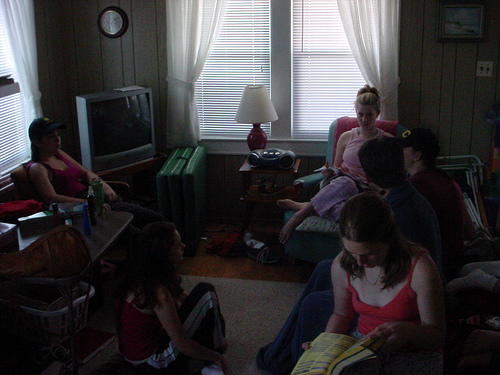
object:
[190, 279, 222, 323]
knee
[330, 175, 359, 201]
knee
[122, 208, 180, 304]
hair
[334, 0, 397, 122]
curtains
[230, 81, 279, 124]
lamp shade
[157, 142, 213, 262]
tables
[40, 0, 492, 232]
wall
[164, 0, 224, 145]
curtain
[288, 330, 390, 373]
book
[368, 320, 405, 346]
hand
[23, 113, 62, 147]
cap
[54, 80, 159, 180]
television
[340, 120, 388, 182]
shirt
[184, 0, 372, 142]
window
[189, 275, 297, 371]
carpet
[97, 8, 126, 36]
clock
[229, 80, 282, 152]
lamp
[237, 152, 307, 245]
table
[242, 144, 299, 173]
stereo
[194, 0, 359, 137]
blinds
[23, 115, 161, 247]
girl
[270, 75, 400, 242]
girl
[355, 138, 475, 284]
people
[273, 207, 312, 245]
foot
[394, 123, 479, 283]
man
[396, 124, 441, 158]
ball cap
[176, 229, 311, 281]
floor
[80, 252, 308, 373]
rug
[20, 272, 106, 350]
basket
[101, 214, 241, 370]
girl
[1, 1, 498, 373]
photo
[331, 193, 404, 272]
head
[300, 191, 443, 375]
girl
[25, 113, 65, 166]
head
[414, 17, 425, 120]
line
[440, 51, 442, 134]
line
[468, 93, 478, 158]
line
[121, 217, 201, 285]
head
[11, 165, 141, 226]
chair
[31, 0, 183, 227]
corner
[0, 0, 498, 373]
room